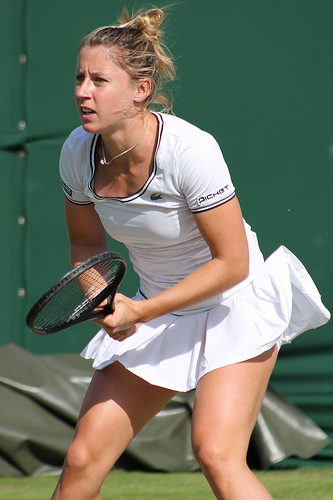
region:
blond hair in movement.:
[102, 9, 182, 71]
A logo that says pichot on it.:
[186, 178, 242, 220]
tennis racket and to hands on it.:
[13, 232, 154, 359]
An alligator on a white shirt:
[143, 182, 175, 208]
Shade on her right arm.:
[29, 111, 114, 282]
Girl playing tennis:
[7, 19, 252, 362]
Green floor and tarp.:
[286, 441, 327, 499]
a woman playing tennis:
[20, 4, 332, 498]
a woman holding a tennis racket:
[18, 3, 331, 495]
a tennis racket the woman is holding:
[19, 246, 140, 343]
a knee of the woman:
[62, 439, 92, 476]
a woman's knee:
[194, 440, 224, 478]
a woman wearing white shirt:
[19, 5, 332, 496]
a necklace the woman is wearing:
[90, 111, 150, 169]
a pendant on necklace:
[97, 157, 105, 166]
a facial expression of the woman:
[70, 47, 134, 135]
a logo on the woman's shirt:
[147, 190, 166, 202]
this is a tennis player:
[27, 20, 271, 498]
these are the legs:
[78, 375, 250, 496]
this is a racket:
[32, 261, 114, 340]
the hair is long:
[112, 4, 167, 62]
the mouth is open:
[77, 101, 99, 118]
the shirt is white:
[179, 150, 206, 170]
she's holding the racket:
[94, 302, 126, 323]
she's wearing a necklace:
[97, 147, 119, 166]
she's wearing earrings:
[135, 96, 144, 102]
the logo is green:
[150, 192, 166, 202]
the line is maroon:
[123, 195, 136, 202]